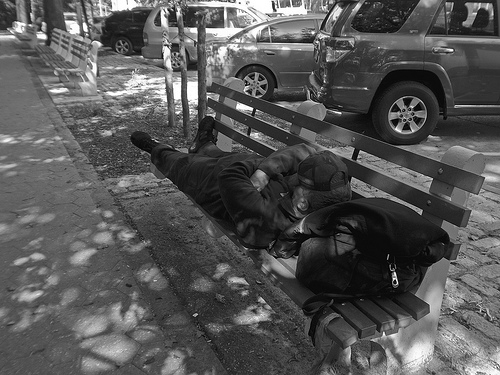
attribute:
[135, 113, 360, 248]
man — sleeping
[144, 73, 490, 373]
bench — wood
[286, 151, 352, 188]
hat — black colored, black in color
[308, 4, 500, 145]
car — parked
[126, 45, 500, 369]
street — brick, black, cabble stone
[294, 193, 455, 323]
backpack — black, black in color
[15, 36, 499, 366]
ground — shadowed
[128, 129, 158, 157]
tennis shoe — black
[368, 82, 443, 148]
tire — black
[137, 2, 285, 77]
mini van — light colored, gray